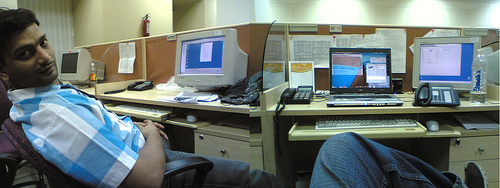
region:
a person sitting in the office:
[308, 130, 488, 186]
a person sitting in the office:
[0, 6, 291, 186]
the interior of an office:
[0, 0, 499, 186]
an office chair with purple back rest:
[1, 117, 213, 187]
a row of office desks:
[0, 19, 499, 186]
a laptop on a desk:
[325, 47, 403, 107]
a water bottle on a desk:
[469, 48, 488, 105]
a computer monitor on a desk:
[174, 28, 248, 100]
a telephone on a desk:
[411, 81, 460, 106]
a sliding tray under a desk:
[287, 112, 459, 140]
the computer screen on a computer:
[59, 52, 79, 76]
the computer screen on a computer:
[179, 40, 225, 72]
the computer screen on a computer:
[331, 49, 389, 88]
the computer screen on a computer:
[420, 41, 474, 80]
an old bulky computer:
[59, 48, 104, 82]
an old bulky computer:
[175, 30, 252, 87]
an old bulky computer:
[407, 34, 490, 92]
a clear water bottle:
[470, 44, 488, 99]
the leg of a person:
[314, 112, 416, 127]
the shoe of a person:
[462, 158, 485, 186]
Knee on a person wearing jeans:
[315, 122, 461, 187]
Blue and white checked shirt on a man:
[12, 83, 144, 170]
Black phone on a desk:
[278, 81, 319, 114]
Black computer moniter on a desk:
[333, 48, 390, 90]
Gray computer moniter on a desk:
[407, 30, 485, 97]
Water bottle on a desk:
[470, 47, 490, 98]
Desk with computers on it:
[58, 29, 267, 115]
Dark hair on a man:
[2, 5, 60, 87]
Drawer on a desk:
[199, 125, 264, 170]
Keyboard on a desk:
[315, 110, 431, 133]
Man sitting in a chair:
[5, 4, 483, 186]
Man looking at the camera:
[0, 8, 75, 85]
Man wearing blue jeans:
[295, 122, 458, 187]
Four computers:
[56, 24, 482, 108]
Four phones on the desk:
[102, 64, 461, 115]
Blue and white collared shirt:
[10, 75, 152, 186]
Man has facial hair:
[25, 55, 79, 81]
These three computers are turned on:
[156, 22, 488, 109]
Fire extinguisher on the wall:
[134, 9, 155, 34]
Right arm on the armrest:
[117, 130, 223, 185]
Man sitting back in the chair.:
[18, 43, 193, 178]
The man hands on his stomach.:
[118, 103, 175, 158]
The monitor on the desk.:
[161, 32, 245, 87]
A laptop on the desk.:
[316, 44, 401, 115]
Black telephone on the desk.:
[273, 60, 326, 110]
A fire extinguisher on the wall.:
[138, 13, 154, 40]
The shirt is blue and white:
[35, 90, 137, 179]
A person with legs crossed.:
[309, 132, 442, 179]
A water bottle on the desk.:
[466, 42, 494, 109]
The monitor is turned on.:
[163, 22, 243, 79]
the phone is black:
[273, 85, 313, 115]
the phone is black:
[413, 82, 460, 109]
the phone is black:
[103, 78, 155, 95]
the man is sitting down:
[0, 6, 249, 186]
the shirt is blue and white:
[3, 76, 147, 186]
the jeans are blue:
[310, 130, 465, 186]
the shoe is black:
[462, 160, 487, 186]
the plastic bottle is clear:
[467, 47, 487, 103]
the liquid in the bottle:
[468, 48, 486, 104]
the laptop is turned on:
[327, 45, 405, 105]